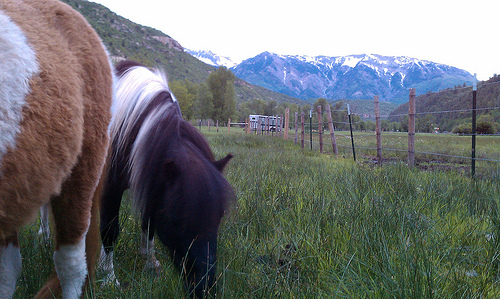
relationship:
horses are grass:
[1, 49, 290, 290] [0, 131, 499, 298]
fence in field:
[197, 72, 500, 183] [0, 119, 493, 293]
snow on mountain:
[339, 54, 360, 68] [228, 30, 496, 110]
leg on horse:
[44, 165, 96, 297] [1, 0, 108, 297]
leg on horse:
[94, 176, 125, 291] [100, 53, 235, 296]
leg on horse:
[91, 185, 123, 279] [100, 53, 235, 296]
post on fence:
[470, 72, 477, 175] [190, 68, 499, 179]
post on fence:
[404, 87, 416, 166] [190, 68, 499, 179]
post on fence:
[322, 102, 337, 154] [190, 68, 499, 179]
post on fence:
[282, 104, 288, 141] [190, 68, 499, 179]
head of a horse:
[159, 161, 242, 288] [110, 49, 239, 293]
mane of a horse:
[106, 45, 176, 229] [68, 36, 268, 290]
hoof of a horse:
[142, 248, 155, 269] [100, 53, 235, 296]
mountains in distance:
[223, 19, 482, 140] [60, 12, 488, 146]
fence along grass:
[190, 68, 499, 179] [5, 123, 497, 293]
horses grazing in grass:
[1, 0, 120, 299] [249, 135, 478, 284]